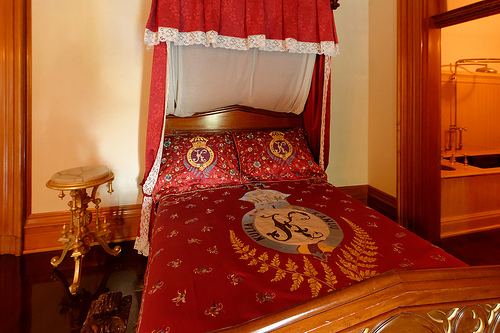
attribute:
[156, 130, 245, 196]
pillow — red, monogrammed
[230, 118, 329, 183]
pillow — red, monogrammed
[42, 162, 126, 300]
table — gold, ornate, marble, three legged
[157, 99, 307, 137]
headboard — wooden, shiny, wood, polished, brown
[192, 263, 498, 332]
footboard — wooden, polished, carved, wood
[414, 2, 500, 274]
doorway — large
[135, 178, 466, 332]
blanket — monogrammed, red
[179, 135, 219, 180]
design — gold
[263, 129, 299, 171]
design — gold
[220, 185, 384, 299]
design — gold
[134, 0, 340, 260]
curtain — red, white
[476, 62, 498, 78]
shower head — metal, silver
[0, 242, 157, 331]
floor — dark, shiny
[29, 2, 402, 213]
wall — beige, white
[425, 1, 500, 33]
beam — wooden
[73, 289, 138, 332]
object — strange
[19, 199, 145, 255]
baseboard — wood, wooden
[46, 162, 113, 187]
top — marble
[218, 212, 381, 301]
wreath — gold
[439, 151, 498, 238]
bathtub — white